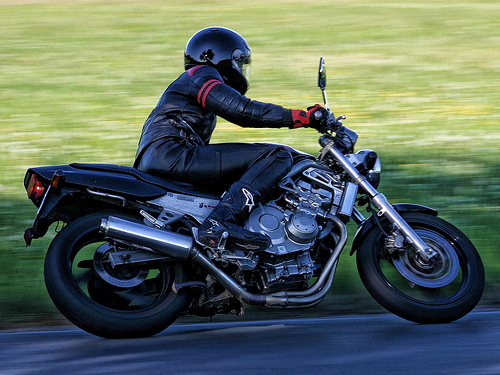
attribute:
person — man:
[138, 26, 328, 248]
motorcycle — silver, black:
[25, 57, 486, 339]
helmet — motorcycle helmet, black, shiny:
[184, 26, 252, 95]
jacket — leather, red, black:
[133, 65, 293, 167]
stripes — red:
[193, 78, 222, 108]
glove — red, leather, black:
[289, 105, 328, 130]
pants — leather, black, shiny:
[134, 137, 317, 194]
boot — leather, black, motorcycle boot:
[194, 182, 272, 253]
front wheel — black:
[357, 213, 485, 323]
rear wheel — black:
[44, 211, 196, 339]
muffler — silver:
[98, 215, 194, 257]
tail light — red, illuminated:
[26, 173, 46, 198]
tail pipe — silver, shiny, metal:
[96, 218, 107, 232]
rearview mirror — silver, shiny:
[317, 58, 328, 103]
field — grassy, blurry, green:
[1, 1, 499, 327]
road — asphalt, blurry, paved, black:
[0, 307, 500, 373]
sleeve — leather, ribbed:
[186, 65, 291, 129]